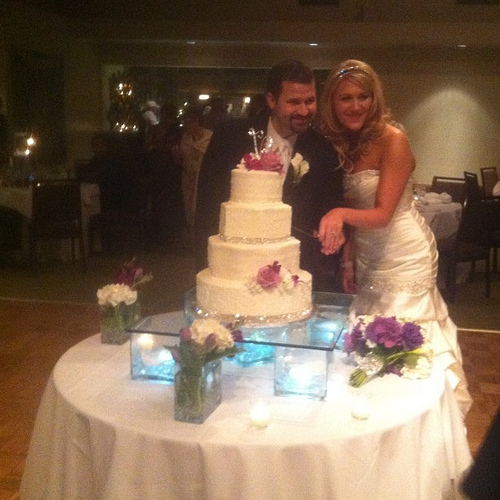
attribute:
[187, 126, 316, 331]
wedding cake — large, white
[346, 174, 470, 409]
wedding dress — long, white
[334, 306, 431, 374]
flowers — purple, white